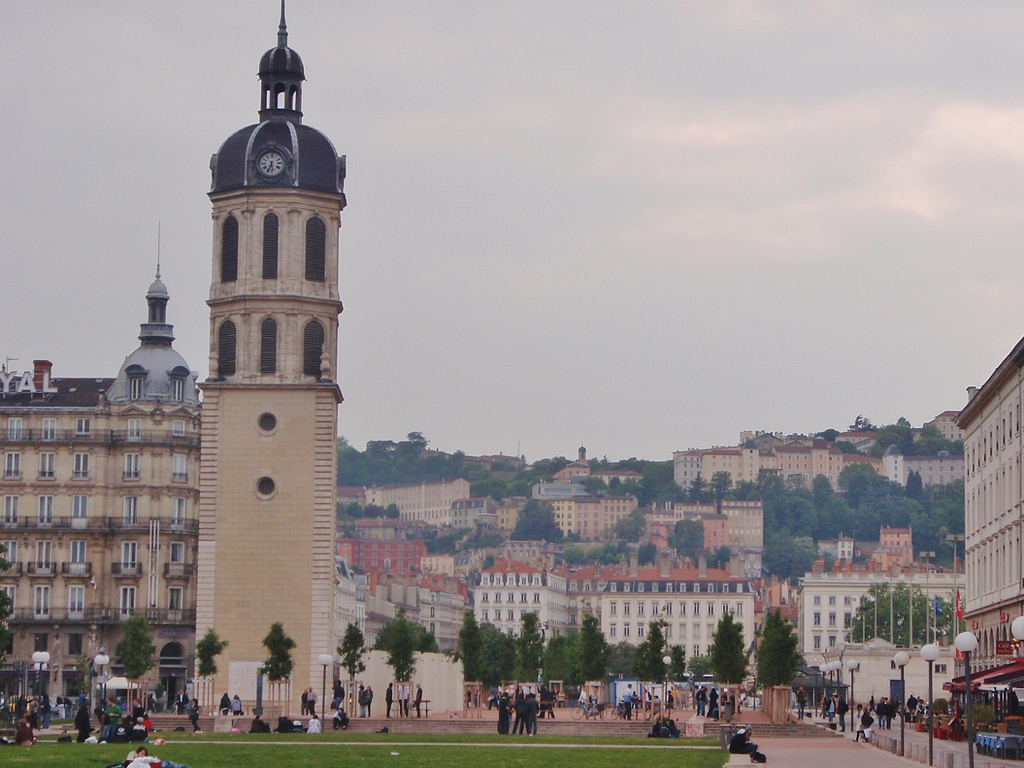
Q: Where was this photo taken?
A: Outside a building.